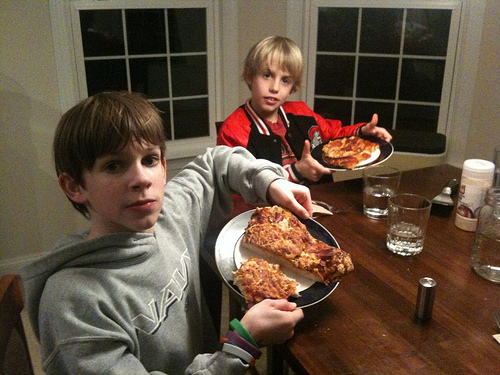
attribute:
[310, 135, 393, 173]
plate — round, black, white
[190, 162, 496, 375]
table — brown, wooden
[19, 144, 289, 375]
sweatshirt — gray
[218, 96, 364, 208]
jacket — red, black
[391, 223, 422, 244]
liquid — clear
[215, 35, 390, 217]
boy — blond, blonde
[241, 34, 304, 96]
hair — blond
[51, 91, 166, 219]
hair — brown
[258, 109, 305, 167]
shirt — red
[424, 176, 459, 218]
spatula — large